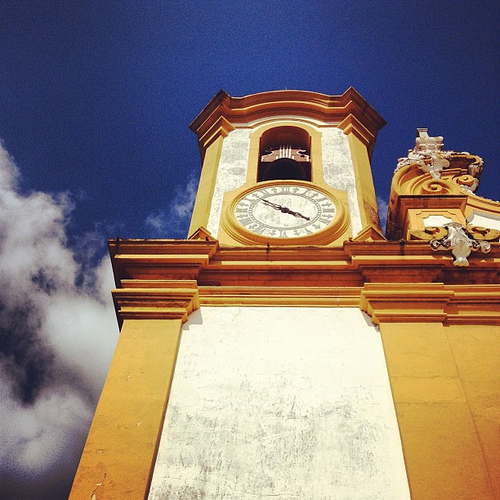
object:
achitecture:
[385, 126, 499, 267]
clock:
[221, 179, 348, 244]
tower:
[64, 89, 497, 498]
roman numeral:
[280, 185, 290, 192]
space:
[186, 311, 354, 500]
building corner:
[106, 237, 139, 306]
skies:
[0, 0, 500, 219]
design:
[321, 128, 354, 190]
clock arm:
[259, 198, 282, 210]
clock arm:
[286, 206, 311, 221]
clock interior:
[232, 183, 336, 239]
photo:
[2, 2, 484, 498]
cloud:
[3, 368, 95, 493]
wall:
[64, 317, 500, 499]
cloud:
[0, 140, 70, 275]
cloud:
[33, 291, 119, 378]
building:
[55, 88, 498, 498]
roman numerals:
[238, 217, 253, 227]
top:
[188, 87, 388, 148]